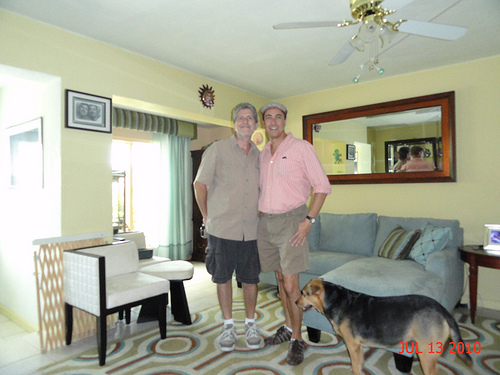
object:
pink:
[260, 142, 304, 210]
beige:
[261, 218, 291, 264]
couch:
[266, 209, 470, 358]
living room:
[0, 1, 500, 372]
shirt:
[195, 132, 273, 244]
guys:
[188, 98, 271, 354]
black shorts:
[203, 232, 263, 285]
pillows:
[377, 225, 420, 260]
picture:
[72, 95, 107, 128]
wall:
[2, 16, 286, 144]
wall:
[42, 74, 124, 269]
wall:
[283, 71, 495, 253]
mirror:
[301, 106, 444, 175]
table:
[453, 238, 500, 324]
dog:
[294, 276, 471, 374]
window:
[113, 126, 173, 253]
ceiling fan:
[256, 2, 474, 84]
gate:
[0, 68, 61, 351]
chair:
[62, 239, 175, 360]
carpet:
[29, 289, 497, 375]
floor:
[123, 249, 247, 335]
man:
[246, 92, 328, 366]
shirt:
[242, 131, 339, 215]